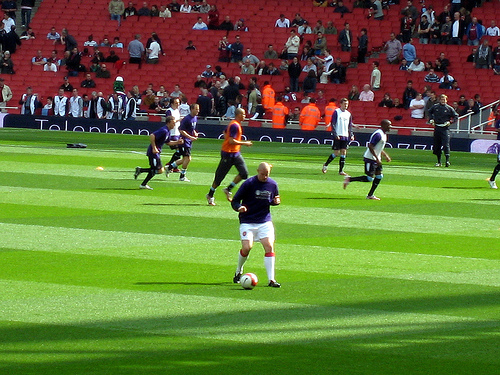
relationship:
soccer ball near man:
[238, 271, 259, 291] [229, 161, 291, 289]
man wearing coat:
[271, 97, 291, 128] [272, 101, 288, 128]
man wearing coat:
[229, 161, 291, 289] [272, 101, 288, 128]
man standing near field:
[428, 93, 460, 167] [1, 122, 496, 373]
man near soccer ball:
[229, 161, 291, 289] [238, 271, 259, 291]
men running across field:
[131, 95, 251, 213] [1, 122, 496, 373]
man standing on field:
[229, 161, 291, 289] [1, 122, 496, 373]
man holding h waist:
[271, 97, 291, 128] [430, 116, 453, 132]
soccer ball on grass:
[238, 271, 259, 291] [6, 129, 494, 371]